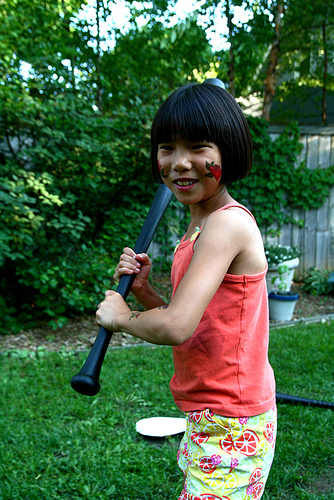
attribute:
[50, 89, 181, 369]
bat — black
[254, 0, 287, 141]
tree — brown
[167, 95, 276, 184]
hair — short, black, jet black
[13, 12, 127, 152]
trees — green, tall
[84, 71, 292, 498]
girl — young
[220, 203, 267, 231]
strap — salmon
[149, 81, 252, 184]
hair — black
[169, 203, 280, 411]
top — orange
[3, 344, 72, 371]
leaves — green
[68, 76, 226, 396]
bat — plastic, black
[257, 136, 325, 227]
plants — green, leafy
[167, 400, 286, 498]
shorts — yellow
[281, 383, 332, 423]
bat — black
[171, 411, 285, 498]
shorts — yellow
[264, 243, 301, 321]
pots — terra cotta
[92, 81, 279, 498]
girl — happy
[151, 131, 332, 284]
fence — wooden